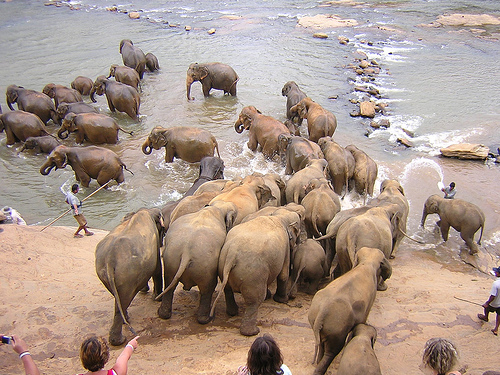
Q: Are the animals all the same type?
A: Yes, all the animals are elephants.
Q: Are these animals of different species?
A: No, all the animals are elephants.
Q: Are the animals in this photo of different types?
A: No, all the animals are elephants.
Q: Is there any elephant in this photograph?
A: Yes, there is an elephant.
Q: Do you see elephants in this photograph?
A: Yes, there is an elephant.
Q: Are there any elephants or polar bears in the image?
A: Yes, there is an elephant.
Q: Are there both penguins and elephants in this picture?
A: No, there is an elephant but no penguins.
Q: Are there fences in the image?
A: No, there are no fences.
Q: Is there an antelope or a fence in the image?
A: No, there are no fences or antelopes.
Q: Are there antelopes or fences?
A: No, there are no fences or antelopes.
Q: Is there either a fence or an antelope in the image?
A: No, there are no fences or antelopes.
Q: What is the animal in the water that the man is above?
A: The animal is an elephant.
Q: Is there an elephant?
A: Yes, there is an elephant.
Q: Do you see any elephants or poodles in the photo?
A: Yes, there is an elephant.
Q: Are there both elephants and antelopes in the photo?
A: No, there is an elephant but no antelopes.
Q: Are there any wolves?
A: No, there are no wolves.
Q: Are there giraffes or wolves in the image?
A: No, there are no wolves or giraffes.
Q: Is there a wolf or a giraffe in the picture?
A: No, there are no wolves or giraffes.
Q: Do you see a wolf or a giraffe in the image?
A: No, there are no wolves or giraffes.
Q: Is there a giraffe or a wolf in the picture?
A: No, there are no wolves or giraffes.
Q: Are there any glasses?
A: No, there are no glasses.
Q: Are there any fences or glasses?
A: No, there are no glasses or fences.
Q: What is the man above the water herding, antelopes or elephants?
A: The man is herding elephants.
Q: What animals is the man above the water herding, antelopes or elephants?
A: The man is herding elephants.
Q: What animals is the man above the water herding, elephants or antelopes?
A: The man is herding elephants.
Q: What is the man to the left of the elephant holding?
A: The man is holding the stick.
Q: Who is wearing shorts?
A: The man is wearing shorts.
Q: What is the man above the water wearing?
A: The man is wearing shorts.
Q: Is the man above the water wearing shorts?
A: Yes, the man is wearing shorts.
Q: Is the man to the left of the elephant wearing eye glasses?
A: No, the man is wearing shorts.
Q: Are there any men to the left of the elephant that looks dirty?
A: Yes, there is a man to the left of the elephant.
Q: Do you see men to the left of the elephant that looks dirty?
A: Yes, there is a man to the left of the elephant.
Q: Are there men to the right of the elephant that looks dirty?
A: No, the man is to the left of the elephant.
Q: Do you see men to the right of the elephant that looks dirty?
A: No, the man is to the left of the elephant.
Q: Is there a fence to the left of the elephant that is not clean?
A: No, there is a man to the left of the elephant.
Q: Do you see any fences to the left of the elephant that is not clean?
A: No, there is a man to the left of the elephant.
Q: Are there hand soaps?
A: No, there are no hand soaps.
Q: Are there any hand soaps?
A: No, there are no hand soaps.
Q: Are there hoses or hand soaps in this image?
A: No, there are no hand soaps or hoses.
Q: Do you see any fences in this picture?
A: No, there are no fences.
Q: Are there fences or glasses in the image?
A: No, there are no fences or glasses.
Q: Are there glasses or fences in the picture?
A: No, there are no fences or glasses.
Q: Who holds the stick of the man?
A: The man holds the stick.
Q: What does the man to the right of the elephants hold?
A: The man holds the stick.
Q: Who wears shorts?
A: The man wears shorts.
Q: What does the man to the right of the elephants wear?
A: The man wears shorts.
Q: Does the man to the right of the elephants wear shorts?
A: Yes, the man wears shorts.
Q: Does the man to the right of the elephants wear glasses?
A: No, the man wears shorts.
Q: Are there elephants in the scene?
A: Yes, there are elephants.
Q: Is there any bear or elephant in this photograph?
A: Yes, there are elephants.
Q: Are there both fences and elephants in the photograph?
A: No, there are elephants but no fences.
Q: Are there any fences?
A: No, there are no fences.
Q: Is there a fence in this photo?
A: No, there are no fences.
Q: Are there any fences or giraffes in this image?
A: No, there are no fences or giraffes.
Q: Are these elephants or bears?
A: These are elephants.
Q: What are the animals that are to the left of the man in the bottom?
A: The animals are elephants.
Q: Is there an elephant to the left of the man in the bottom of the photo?
A: Yes, there are elephants to the left of the man.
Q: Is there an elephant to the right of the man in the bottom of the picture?
A: No, the elephants are to the left of the man.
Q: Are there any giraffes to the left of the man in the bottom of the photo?
A: No, there are elephants to the left of the man.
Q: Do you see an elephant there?
A: Yes, there are elephants.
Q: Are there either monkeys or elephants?
A: Yes, there are elephants.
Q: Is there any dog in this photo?
A: No, there are no dogs.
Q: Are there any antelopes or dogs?
A: No, there are no dogs or antelopes.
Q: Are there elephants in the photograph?
A: Yes, there is an elephant.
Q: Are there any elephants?
A: Yes, there is an elephant.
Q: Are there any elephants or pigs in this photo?
A: Yes, there is an elephant.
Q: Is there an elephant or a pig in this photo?
A: Yes, there is an elephant.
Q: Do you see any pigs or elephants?
A: Yes, there is an elephant.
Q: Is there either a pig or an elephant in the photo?
A: Yes, there is an elephant.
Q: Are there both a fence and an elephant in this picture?
A: No, there is an elephant but no fences.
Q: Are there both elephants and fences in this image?
A: No, there is an elephant but no fences.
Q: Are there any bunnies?
A: No, there are no bunnies.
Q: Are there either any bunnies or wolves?
A: No, there are no bunnies or wolves.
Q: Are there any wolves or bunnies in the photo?
A: No, there are no bunnies or wolves.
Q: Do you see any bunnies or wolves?
A: No, there are no bunnies or wolves.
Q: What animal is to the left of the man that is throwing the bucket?
A: The animal is an elephant.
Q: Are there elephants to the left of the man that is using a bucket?
A: Yes, there is an elephant to the left of the man.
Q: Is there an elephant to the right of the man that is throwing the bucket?
A: No, the elephant is to the left of the man.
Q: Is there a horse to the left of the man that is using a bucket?
A: No, there is an elephant to the left of the man.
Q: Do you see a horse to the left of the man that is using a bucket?
A: No, there is an elephant to the left of the man.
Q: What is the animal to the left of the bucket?
A: The animal is an elephant.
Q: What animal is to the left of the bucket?
A: The animal is an elephant.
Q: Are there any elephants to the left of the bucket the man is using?
A: Yes, there is an elephant to the left of the bucket.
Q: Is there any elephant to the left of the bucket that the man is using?
A: Yes, there is an elephant to the left of the bucket.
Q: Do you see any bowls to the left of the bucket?
A: No, there is an elephant to the left of the bucket.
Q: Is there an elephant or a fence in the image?
A: Yes, there is an elephant.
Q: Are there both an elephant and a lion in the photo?
A: No, there is an elephant but no lions.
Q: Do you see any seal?
A: No, there are no seals.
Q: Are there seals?
A: No, there are no seals.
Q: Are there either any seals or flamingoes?
A: No, there are no seals or flamingoes.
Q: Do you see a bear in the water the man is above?
A: No, there is an elephant in the water.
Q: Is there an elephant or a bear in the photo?
A: Yes, there is an elephant.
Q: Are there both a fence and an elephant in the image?
A: No, there is an elephant but no fences.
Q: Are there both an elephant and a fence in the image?
A: No, there is an elephant but no fences.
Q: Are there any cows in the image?
A: No, there are no cows.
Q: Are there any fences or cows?
A: No, there are no cows or fences.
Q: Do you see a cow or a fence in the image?
A: No, there are no cows or fences.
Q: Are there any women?
A: Yes, there is a woman.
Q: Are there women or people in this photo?
A: Yes, there is a woman.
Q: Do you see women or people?
A: Yes, there is a woman.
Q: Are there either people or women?
A: Yes, there is a woman.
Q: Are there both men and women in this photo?
A: Yes, there are both a woman and a man.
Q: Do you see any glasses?
A: No, there are no glasses.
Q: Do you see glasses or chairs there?
A: No, there are no glasses or chairs.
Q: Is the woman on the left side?
A: Yes, the woman is on the left of the image.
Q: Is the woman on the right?
A: No, the woman is on the left of the image.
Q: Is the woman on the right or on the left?
A: The woman is on the left of the image.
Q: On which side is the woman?
A: The woman is on the left of the image.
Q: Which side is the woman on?
A: The woman is on the left of the image.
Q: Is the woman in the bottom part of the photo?
A: Yes, the woman is in the bottom of the image.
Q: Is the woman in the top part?
A: No, the woman is in the bottom of the image.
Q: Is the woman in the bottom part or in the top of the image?
A: The woman is in the bottom of the image.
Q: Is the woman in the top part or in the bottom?
A: The woman is in the bottom of the image.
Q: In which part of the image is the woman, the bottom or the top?
A: The woman is in the bottom of the image.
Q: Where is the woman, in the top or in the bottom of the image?
A: The woman is in the bottom of the image.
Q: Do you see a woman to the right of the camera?
A: Yes, there is a woman to the right of the camera.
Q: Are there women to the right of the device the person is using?
A: Yes, there is a woman to the right of the camera.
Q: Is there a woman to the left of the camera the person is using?
A: No, the woman is to the right of the camera.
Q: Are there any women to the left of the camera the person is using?
A: No, the woman is to the right of the camera.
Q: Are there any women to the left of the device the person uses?
A: No, the woman is to the right of the camera.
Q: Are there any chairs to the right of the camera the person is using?
A: No, there is a woman to the right of the camera.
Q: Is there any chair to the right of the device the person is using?
A: No, there is a woman to the right of the camera.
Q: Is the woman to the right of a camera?
A: Yes, the woman is to the right of a camera.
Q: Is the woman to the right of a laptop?
A: No, the woman is to the right of a camera.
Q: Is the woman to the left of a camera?
A: No, the woman is to the right of a camera.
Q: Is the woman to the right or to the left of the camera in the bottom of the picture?
A: The woman is to the right of the camera.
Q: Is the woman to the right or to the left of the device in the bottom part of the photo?
A: The woman is to the right of the camera.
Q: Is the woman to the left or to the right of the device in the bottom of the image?
A: The woman is to the right of the camera.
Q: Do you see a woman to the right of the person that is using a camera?
A: Yes, there is a woman to the right of the person.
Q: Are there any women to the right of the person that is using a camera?
A: Yes, there is a woman to the right of the person.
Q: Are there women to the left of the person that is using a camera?
A: No, the woman is to the right of the person.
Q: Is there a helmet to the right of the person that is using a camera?
A: No, there is a woman to the right of the person.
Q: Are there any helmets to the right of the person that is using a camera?
A: No, there is a woman to the right of the person.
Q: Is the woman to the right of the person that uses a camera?
A: Yes, the woman is to the right of the person.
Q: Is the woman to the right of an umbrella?
A: No, the woman is to the right of the person.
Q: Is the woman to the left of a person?
A: No, the woman is to the right of a person.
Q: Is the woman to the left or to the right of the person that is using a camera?
A: The woman is to the right of the person.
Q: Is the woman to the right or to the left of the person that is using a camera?
A: The woman is to the right of the person.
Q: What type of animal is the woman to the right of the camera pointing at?
A: The woman is pointing at the elephant.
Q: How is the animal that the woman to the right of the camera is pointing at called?
A: The animal is an elephant.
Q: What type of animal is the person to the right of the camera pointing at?
A: The woman is pointing at the elephant.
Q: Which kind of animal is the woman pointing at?
A: The woman is pointing at the elephant.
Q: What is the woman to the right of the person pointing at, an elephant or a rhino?
A: The woman is pointing at an elephant.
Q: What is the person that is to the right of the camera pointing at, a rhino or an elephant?
A: The woman is pointing at an elephant.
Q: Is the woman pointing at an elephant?
A: Yes, the woman is pointing at an elephant.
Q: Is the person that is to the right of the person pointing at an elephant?
A: Yes, the woman is pointing at an elephant.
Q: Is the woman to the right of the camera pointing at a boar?
A: No, the woman is pointing at an elephant.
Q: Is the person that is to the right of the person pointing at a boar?
A: No, the woman is pointing at an elephant.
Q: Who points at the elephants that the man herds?
A: The woman points at the elephants.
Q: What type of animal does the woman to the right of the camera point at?
A: The woman points at the elephants.